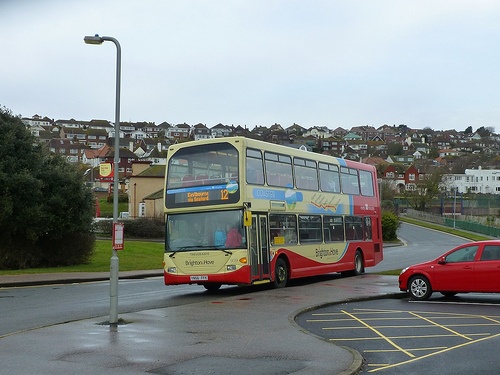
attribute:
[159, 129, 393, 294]
bus — double decker , yellow, red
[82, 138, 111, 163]
house — yellow, red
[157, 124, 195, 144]
house — yellow, red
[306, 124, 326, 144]
house — red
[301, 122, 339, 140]
house — red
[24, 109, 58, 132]
house — red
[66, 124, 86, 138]
house — red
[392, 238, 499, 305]
car — red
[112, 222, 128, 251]
sign — red, white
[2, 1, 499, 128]
sky — light, blue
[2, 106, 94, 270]
bush — evergreen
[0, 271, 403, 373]
sidewalk — concrete, wet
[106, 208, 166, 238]
hedges — low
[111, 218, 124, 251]
sign — white, red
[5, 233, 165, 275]
lawn — grass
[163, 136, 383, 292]
bus — red, yellow, double decker, large, double-decker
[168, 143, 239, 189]
window — big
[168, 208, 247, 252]
window — big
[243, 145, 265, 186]
window — big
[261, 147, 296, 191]
window — big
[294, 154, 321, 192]
window — big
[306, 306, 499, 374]
lines — yellow, criss-crossed, painted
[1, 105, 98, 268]
tree — large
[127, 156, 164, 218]
building — large, tan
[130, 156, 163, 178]
roof — green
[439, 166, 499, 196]
building — big, white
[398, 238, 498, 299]
car — red, parked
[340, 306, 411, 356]
line — yellow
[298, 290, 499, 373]
pavement — asphalt, dark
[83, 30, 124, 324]
street light — tall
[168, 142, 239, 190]
glass — clear 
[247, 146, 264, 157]
glass — clear 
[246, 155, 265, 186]
glass — clear 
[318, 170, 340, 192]
glass — clear 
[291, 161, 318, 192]
glass — clear, clean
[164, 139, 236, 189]
glass — clear, clean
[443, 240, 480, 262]
glass — clear, clean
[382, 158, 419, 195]
home — large, brick